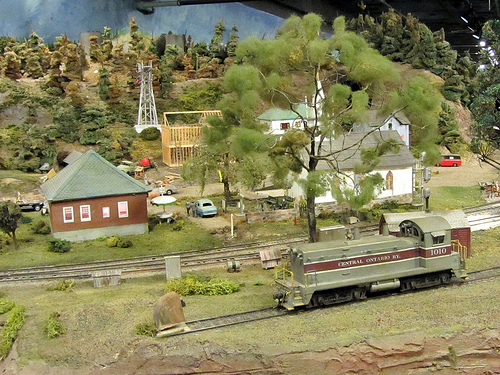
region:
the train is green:
[276, 216, 461, 315]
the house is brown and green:
[41, 147, 153, 248]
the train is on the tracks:
[153, 263, 498, 339]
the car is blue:
[196, 198, 218, 214]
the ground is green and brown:
[0, 163, 499, 373]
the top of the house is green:
[38, 150, 150, 202]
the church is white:
[284, 165, 412, 202]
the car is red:
[437, 156, 460, 166]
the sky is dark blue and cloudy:
[0, 0, 330, 45]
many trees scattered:
[0, 15, 498, 240]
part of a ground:
[359, 301, 402, 337]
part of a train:
[263, 270, 325, 327]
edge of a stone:
[399, 336, 421, 361]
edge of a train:
[318, 232, 378, 292]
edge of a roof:
[86, 183, 120, 210]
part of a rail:
[231, 293, 285, 347]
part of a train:
[267, 248, 317, 313]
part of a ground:
[316, 301, 361, 341]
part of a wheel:
[323, 284, 363, 311]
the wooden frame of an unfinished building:
[158, 108, 238, 167]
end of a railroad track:
[137, 293, 204, 338]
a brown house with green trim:
[37, 143, 153, 244]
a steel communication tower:
[133, 58, 165, 134]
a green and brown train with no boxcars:
[271, 217, 468, 313]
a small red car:
[435, 153, 465, 166]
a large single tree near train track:
[185, 13, 443, 245]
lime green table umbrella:
[150, 191, 177, 213]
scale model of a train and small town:
[0, 1, 497, 373]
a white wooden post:
[229, 214, 236, 241]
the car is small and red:
[435, 152, 462, 172]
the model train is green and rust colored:
[265, 214, 472, 309]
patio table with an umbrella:
[151, 190, 175, 226]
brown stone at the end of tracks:
[151, 291, 198, 340]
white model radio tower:
[131, 54, 163, 129]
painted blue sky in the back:
[10, 2, 108, 29]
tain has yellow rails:
[451, 237, 469, 270]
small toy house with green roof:
[40, 147, 150, 239]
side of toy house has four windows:
[55, 199, 134, 224]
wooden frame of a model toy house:
[157, 109, 228, 166]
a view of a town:
[9, 20, 473, 317]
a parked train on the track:
[263, 203, 470, 328]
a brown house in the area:
[30, 146, 167, 255]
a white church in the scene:
[290, 91, 429, 208]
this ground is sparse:
[13, 265, 497, 371]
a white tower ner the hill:
[116, 56, 168, 139]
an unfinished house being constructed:
[158, 94, 233, 174]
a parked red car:
[428, 138, 466, 177]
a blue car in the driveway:
[178, 193, 218, 230]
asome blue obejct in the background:
[18, 5, 310, 65]